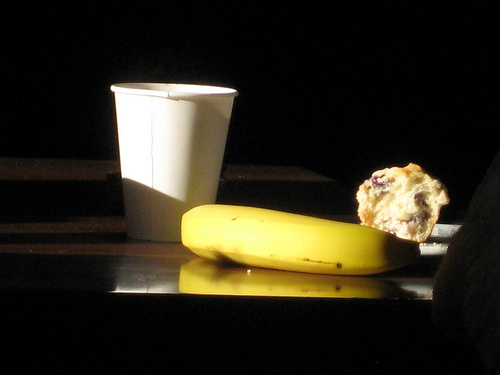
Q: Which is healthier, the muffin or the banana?
A: The banana is healthier than the muffin.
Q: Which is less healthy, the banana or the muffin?
A: The muffin is less healthy than the banana.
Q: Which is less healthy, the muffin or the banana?
A: The muffin is less healthy than the banana.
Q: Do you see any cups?
A: Yes, there is a cup.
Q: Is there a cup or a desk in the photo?
A: Yes, there is a cup.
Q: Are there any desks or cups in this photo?
A: Yes, there is a cup.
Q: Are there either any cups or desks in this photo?
A: Yes, there is a cup.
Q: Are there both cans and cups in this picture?
A: No, there is a cup but no cans.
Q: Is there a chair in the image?
A: No, there are no chairs.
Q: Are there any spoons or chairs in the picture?
A: No, there are no chairs or spoons.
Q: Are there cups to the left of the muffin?
A: Yes, there is a cup to the left of the muffin.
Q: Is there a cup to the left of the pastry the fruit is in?
A: Yes, there is a cup to the left of the muffin.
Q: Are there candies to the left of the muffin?
A: No, there is a cup to the left of the muffin.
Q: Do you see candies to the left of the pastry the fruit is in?
A: No, there is a cup to the left of the muffin.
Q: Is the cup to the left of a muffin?
A: Yes, the cup is to the left of a muffin.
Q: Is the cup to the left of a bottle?
A: No, the cup is to the left of a muffin.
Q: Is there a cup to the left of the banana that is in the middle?
A: Yes, there is a cup to the left of the banana.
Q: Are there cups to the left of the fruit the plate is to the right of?
A: Yes, there is a cup to the left of the banana.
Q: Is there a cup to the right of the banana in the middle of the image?
A: No, the cup is to the left of the banana.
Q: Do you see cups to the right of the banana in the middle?
A: No, the cup is to the left of the banana.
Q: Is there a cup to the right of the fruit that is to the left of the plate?
A: No, the cup is to the left of the banana.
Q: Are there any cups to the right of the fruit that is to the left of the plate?
A: No, the cup is to the left of the banana.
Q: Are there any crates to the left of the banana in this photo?
A: No, there is a cup to the left of the banana.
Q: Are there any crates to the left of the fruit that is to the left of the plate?
A: No, there is a cup to the left of the banana.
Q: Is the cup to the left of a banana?
A: Yes, the cup is to the left of a banana.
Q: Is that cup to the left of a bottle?
A: No, the cup is to the left of a banana.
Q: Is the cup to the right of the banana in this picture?
A: No, the cup is to the left of the banana.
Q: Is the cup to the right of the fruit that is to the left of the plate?
A: No, the cup is to the left of the banana.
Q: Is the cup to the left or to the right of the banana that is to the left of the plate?
A: The cup is to the left of the banana.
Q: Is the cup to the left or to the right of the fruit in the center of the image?
A: The cup is to the left of the banana.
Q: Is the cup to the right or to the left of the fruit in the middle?
A: The cup is to the left of the banana.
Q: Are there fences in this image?
A: No, there are no fences.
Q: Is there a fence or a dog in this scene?
A: No, there are no fences or dogs.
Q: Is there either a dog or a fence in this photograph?
A: No, there are no fences or dogs.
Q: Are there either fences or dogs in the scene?
A: No, there are no fences or dogs.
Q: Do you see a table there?
A: Yes, there is a table.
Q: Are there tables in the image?
A: Yes, there is a table.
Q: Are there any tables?
A: Yes, there is a table.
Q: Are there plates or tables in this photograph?
A: Yes, there is a table.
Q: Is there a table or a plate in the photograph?
A: Yes, there is a table.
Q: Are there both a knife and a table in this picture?
A: No, there is a table but no knives.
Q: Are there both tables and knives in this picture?
A: No, there is a table but no knives.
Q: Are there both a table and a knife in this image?
A: No, there is a table but no knives.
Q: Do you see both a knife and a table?
A: No, there is a table but no knives.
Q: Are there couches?
A: No, there are no couches.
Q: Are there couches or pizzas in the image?
A: No, there are no couches or pizzas.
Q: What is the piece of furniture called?
A: The piece of furniture is a table.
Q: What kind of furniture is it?
A: The piece of furniture is a table.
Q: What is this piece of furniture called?
A: This is a table.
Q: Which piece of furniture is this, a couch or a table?
A: This is a table.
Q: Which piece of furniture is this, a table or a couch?
A: This is a table.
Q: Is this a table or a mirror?
A: This is a table.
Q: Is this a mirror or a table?
A: This is a table.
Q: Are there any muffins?
A: Yes, there is a muffin.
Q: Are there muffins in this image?
A: Yes, there is a muffin.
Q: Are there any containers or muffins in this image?
A: Yes, there is a muffin.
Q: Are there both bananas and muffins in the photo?
A: Yes, there are both a muffin and a banana.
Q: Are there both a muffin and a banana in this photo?
A: Yes, there are both a muffin and a banana.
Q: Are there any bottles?
A: No, there are no bottles.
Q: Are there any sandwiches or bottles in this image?
A: No, there are no bottles or sandwiches.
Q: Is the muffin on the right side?
A: Yes, the muffin is on the right of the image.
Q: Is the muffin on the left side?
A: No, the muffin is on the right of the image.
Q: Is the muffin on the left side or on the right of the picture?
A: The muffin is on the right of the image.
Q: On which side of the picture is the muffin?
A: The muffin is on the right of the image.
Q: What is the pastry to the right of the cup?
A: The pastry is a muffin.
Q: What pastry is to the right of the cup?
A: The pastry is a muffin.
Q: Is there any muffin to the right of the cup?
A: Yes, there is a muffin to the right of the cup.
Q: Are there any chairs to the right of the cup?
A: No, there is a muffin to the right of the cup.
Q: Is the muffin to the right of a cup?
A: Yes, the muffin is to the right of a cup.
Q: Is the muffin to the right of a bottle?
A: No, the muffin is to the right of a cup.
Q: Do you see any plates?
A: Yes, there is a plate.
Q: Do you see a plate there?
A: Yes, there is a plate.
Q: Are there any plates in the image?
A: Yes, there is a plate.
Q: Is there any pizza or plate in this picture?
A: Yes, there is a plate.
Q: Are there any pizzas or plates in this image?
A: Yes, there is a plate.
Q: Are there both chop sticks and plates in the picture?
A: No, there is a plate but no chopsticks.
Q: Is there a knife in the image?
A: No, there are no knives.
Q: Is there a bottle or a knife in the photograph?
A: No, there are no knives or bottles.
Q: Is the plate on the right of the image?
A: Yes, the plate is on the right of the image.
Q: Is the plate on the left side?
A: No, the plate is on the right of the image.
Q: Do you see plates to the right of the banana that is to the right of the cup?
A: Yes, there is a plate to the right of the banana.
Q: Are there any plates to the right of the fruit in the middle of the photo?
A: Yes, there is a plate to the right of the banana.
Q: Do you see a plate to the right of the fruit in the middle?
A: Yes, there is a plate to the right of the banana.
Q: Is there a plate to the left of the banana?
A: No, the plate is to the right of the banana.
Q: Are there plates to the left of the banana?
A: No, the plate is to the right of the banana.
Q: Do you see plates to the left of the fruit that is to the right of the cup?
A: No, the plate is to the right of the banana.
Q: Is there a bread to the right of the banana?
A: No, there is a plate to the right of the banana.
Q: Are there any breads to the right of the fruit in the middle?
A: No, there is a plate to the right of the banana.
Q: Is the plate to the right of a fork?
A: No, the plate is to the right of the banana.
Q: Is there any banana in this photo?
A: Yes, there is a banana.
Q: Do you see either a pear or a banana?
A: Yes, there is a banana.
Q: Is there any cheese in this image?
A: No, there is no cheese.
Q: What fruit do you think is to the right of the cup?
A: The fruit is a banana.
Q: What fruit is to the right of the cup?
A: The fruit is a banana.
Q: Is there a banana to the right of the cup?
A: Yes, there is a banana to the right of the cup.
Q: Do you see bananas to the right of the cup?
A: Yes, there is a banana to the right of the cup.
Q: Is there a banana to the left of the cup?
A: No, the banana is to the right of the cup.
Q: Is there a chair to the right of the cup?
A: No, there is a banana to the right of the cup.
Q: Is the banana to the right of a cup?
A: Yes, the banana is to the right of a cup.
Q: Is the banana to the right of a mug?
A: No, the banana is to the right of a cup.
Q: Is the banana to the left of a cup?
A: No, the banana is to the right of a cup.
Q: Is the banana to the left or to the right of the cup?
A: The banana is to the right of the cup.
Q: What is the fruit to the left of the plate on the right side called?
A: The fruit is a banana.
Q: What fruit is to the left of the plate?
A: The fruit is a banana.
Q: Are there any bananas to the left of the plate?
A: Yes, there is a banana to the left of the plate.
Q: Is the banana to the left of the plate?
A: Yes, the banana is to the left of the plate.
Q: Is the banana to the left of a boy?
A: No, the banana is to the left of the plate.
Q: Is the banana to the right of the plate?
A: No, the banana is to the left of the plate.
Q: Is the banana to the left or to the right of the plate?
A: The banana is to the left of the plate.